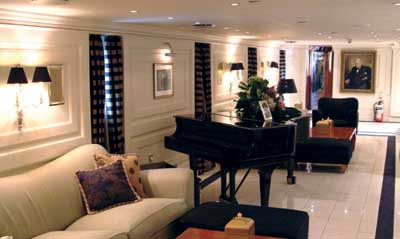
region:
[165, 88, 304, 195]
piano in the living room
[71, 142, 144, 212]
pillows on the sofa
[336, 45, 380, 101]
picture on the wall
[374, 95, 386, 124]
fire extinguisher on the ground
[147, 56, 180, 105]
small picture on the wall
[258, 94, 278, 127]
picture on the piano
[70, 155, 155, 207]
pillow on the sofa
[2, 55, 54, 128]
lights on the wall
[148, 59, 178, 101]
picture on the wall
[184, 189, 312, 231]
ottoman in front of the sofa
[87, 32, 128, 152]
curtain on the wall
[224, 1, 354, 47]
lights on the ceiling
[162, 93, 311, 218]
the baby grand piano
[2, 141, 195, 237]
off white sofa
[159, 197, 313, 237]
the black coffee table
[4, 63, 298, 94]
the black lamp shades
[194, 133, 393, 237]
the shiny floors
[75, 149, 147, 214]
the pillows on the couch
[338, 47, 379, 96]
personalized picture on the wall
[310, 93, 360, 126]
a black chair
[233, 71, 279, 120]
a person sitting down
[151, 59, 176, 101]
a frame on the wall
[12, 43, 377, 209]
room in a house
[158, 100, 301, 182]
piano in the room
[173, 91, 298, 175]
black piano in room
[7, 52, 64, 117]
light above the couch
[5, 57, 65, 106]
two lights above couch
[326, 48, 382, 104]
painting on the wall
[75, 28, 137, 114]
curtains on the window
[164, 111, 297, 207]
A black piano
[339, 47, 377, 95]
Brown painting on a wall of a man in a suit.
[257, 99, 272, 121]
Picture on top of a piano.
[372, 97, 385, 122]
Red and white fire extinguisher.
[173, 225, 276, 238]
A brown table in front of a couch.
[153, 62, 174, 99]
Picture hanging on the wall beside a piano.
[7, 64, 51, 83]
Two black mini lampshades over a white couch.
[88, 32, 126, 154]
Blue and white curtains next to a couch.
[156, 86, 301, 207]
Piano in the living room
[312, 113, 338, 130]
box on top of the coffee table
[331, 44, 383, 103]
portrait of a man on the wall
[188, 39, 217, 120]
curtain hanging on the wall